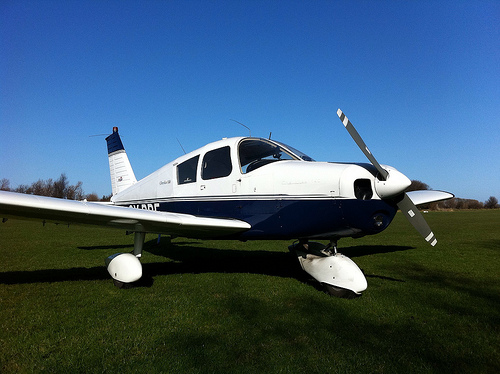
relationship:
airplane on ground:
[44, 109, 468, 301] [36, 308, 144, 366]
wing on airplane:
[20, 191, 234, 242] [44, 109, 468, 301]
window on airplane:
[202, 151, 233, 178] [44, 109, 468, 301]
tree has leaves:
[484, 191, 498, 211] [45, 181, 69, 190]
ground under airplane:
[36, 308, 144, 366] [44, 109, 468, 301]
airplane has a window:
[44, 109, 468, 301] [202, 151, 233, 178]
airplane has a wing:
[44, 109, 468, 301] [20, 191, 234, 242]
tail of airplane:
[98, 124, 141, 188] [44, 109, 468, 301]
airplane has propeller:
[44, 109, 468, 301] [331, 107, 460, 254]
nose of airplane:
[397, 170, 414, 192] [0, 109, 455, 296]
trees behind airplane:
[29, 171, 96, 201] [0, 109, 455, 296]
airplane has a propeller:
[44, 109, 468, 301] [331, 107, 460, 254]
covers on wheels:
[108, 256, 142, 276] [329, 282, 349, 297]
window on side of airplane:
[202, 151, 233, 178] [0, 109, 455, 296]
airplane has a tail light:
[44, 109, 468, 301] [106, 125, 125, 135]